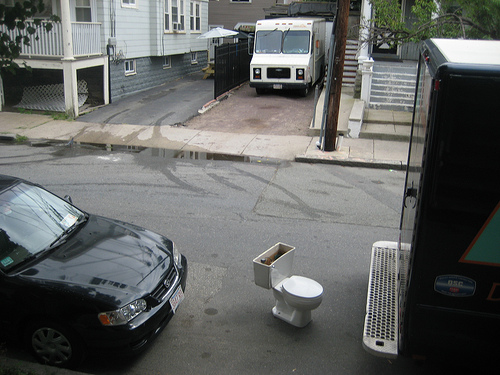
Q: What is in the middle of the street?
A: It is a toilet.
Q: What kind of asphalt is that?
A: It is black asphalt.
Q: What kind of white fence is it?
A: It is a fence located around a home.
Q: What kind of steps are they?
A: They are white steps.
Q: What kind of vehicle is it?
A: It is a Toyota Tercel.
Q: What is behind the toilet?
A: A black car.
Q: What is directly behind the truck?
A: A toilet.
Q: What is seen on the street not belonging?
A: A toilet.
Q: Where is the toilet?
A: In the street.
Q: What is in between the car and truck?
A: A toilet.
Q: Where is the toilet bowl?
A: In the street.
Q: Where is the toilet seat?
A: Down.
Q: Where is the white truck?
A: Across the street.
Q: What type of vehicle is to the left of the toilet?
A: A car.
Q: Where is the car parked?
A: Street.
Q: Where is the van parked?
A: Driveway.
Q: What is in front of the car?
A: Toilet.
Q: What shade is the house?
A: Gray and white.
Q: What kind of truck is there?
A: Box.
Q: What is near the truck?
A: Tree.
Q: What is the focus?
A: Toilet in the street.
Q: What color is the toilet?
A: White.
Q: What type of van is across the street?
A: Fedex.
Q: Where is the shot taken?
A: Sidewalk.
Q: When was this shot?
A: Daytime.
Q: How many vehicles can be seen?
A: 3.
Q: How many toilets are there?
A: 1.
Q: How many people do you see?
A: 0.